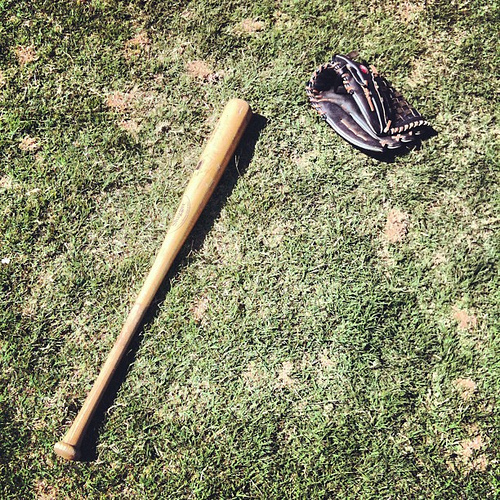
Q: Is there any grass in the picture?
A: Yes, there is grass.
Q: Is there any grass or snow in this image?
A: Yes, there is grass.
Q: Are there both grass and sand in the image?
A: No, there is grass but no sand.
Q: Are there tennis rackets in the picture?
A: No, there are no tennis rackets.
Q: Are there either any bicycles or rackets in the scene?
A: No, there are no rackets or bicycles.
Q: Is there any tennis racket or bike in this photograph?
A: No, there are no rackets or bikes.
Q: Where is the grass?
A: The grass is on the ground.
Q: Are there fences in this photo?
A: No, there are no fences.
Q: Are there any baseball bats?
A: Yes, there is a baseball bat.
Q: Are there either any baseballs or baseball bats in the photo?
A: Yes, there is a baseball bat.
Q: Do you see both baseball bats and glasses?
A: No, there is a baseball bat but no glasses.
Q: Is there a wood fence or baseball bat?
A: Yes, there is a wood baseball bat.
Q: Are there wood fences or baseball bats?
A: Yes, there is a wood baseball bat.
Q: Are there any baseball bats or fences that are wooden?
A: Yes, the baseball bat is wooden.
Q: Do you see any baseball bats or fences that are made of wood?
A: Yes, the baseball bat is made of wood.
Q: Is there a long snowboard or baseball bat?
A: Yes, there is a long baseball bat.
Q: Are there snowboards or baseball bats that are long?
A: Yes, the baseball bat is long.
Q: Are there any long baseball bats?
A: Yes, there is a long baseball bat.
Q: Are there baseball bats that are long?
A: Yes, there is a baseball bat that is long.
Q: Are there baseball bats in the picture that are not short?
A: Yes, there is a long baseball bat.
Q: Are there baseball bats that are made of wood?
A: Yes, there is a baseball bat that is made of wood.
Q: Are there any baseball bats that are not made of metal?
A: Yes, there is a baseball bat that is made of wood.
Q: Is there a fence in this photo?
A: No, there are no fences.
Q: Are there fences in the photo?
A: No, there are no fences.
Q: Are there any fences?
A: No, there are no fences.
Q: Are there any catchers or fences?
A: No, there are no fences or catchers.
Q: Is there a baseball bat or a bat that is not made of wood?
A: No, there is a baseball bat but it is made of wood.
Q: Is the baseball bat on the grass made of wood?
A: Yes, the baseball bat is made of wood.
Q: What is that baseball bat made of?
A: The baseball bat is made of wood.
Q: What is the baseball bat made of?
A: The baseball bat is made of wood.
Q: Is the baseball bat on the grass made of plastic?
A: No, the baseball bat is made of wood.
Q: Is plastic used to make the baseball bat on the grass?
A: No, the baseball bat is made of wood.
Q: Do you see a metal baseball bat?
A: No, there is a baseball bat but it is made of wood.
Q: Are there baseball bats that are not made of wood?
A: No, there is a baseball bat but it is made of wood.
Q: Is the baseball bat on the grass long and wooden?
A: Yes, the baseball bat is long and wooden.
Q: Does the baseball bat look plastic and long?
A: No, the baseball bat is long but wooden.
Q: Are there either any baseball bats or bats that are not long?
A: No, there is a baseball bat but it is long.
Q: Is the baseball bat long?
A: Yes, the baseball bat is long.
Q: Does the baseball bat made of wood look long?
A: Yes, the baseball bat is long.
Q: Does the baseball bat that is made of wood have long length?
A: Yes, the baseball bat is long.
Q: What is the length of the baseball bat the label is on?
A: The baseball bat is long.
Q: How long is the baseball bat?
A: The baseball bat is long.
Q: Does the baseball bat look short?
A: No, the baseball bat is long.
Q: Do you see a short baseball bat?
A: No, there is a baseball bat but it is long.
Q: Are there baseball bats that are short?
A: No, there is a baseball bat but it is long.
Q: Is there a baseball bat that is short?
A: No, there is a baseball bat but it is long.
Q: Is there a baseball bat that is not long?
A: No, there is a baseball bat but it is long.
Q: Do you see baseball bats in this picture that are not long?
A: No, there is a baseball bat but it is long.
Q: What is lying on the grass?
A: The baseball bat is lying on the grass.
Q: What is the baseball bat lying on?
A: The baseball bat is lying on the grass.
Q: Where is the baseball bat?
A: The baseball bat is on the grass.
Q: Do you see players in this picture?
A: No, there are no players.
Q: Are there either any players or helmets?
A: No, there are no players or helmets.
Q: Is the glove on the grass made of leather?
A: Yes, the glove is made of leather.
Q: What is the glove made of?
A: The glove is made of leather.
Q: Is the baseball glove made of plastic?
A: No, the glove is made of leather.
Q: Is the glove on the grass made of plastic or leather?
A: The glove is made of leather.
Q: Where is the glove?
A: The glove is on the grass.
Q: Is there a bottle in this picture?
A: No, there are no bottles.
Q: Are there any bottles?
A: No, there are no bottles.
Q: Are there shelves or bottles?
A: No, there are no bottles or shelves.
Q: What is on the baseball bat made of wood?
A: The label is on the baseball bat.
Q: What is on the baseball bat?
A: The label is on the baseball bat.